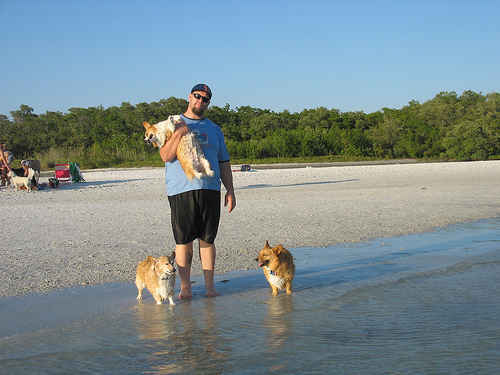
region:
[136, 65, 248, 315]
man standing in the water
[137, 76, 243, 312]
man carrying a small dog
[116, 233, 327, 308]
two small dogs standing in the water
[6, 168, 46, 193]
dog sanding on the sand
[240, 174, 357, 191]
skinny shadow on the ground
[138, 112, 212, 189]
dog with its head tilted back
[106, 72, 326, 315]
a man and three dogs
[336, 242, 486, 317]
extremely small wave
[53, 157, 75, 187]
red and white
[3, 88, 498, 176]
line of thick, green trees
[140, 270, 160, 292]
the dog is brown and white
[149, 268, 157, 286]
the dog is brown and white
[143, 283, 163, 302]
the dog is brown and white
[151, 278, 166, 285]
the dog is brown and white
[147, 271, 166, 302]
the dog is brown and white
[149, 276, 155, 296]
the dog is brown and white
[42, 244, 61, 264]
THE PEBBLE IS WHITE AND BROWN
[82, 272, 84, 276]
THE PEBBLE IS WHITE AND BROWN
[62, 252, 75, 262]
THE PEBBLE IS WHITE AND BROWN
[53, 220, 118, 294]
THE PEBBLE IS WHITE AND BROWN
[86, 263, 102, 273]
THE PEBBLE IS WHITE AND BROWN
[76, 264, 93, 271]
THE PEBBLE IS WHITE AND BROWN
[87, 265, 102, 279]
THE PEBBLE IS WHITE AND BROWN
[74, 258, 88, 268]
THE PEBBLE IS WHITE AND BROWN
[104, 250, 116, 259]
THE PEBBLE IS WHITE AND BROWN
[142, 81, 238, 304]
man in blue shirt holding a dog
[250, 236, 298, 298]
dog standing in water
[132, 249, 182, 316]
brown and white dog standing in water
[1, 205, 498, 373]
shoreline of a beach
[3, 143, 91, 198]
people on a beach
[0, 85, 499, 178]
green trees in the background behind the beach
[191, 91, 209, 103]
sunglasses on man in blue shirt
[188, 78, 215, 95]
hat on man in blue shirt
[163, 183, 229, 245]
black short man is wearing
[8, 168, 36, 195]
white dog standing on beach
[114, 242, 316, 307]
two dogs in the water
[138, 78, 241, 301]
man holding a dog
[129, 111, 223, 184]
dog stretched out with its head tilted back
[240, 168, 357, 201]
shadow on the ground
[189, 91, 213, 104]
thin, dark sunglasses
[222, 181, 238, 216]
hand down by side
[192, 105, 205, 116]
thick goatee on the chin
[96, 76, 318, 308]
three dogs and a man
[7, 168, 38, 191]
dog standing on the beach